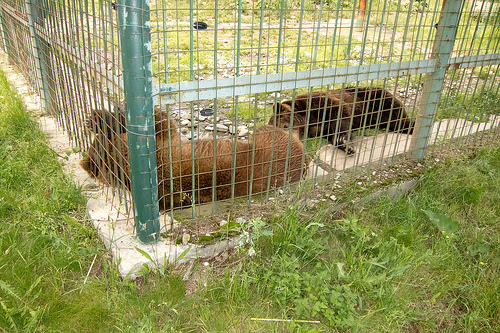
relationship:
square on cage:
[228, 141, 257, 172] [0, 3, 496, 249]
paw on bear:
[388, 114, 406, 131] [268, 84, 411, 155]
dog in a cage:
[71, 95, 290, 204] [155, 0, 408, 203]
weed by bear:
[0, 0, 499, 333] [79, 98, 304, 208]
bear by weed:
[78, 103, 312, 212] [274, 238, 325, 299]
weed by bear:
[0, 0, 499, 333] [72, 91, 296, 204]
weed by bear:
[0, 0, 499, 333] [83, 89, 322, 193]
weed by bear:
[0, 0, 499, 333] [99, 69, 304, 198]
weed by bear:
[339, 225, 419, 294] [63, 95, 313, 202]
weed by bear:
[0, 0, 499, 333] [75, 92, 298, 184]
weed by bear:
[0, 0, 499, 333] [76, 105, 306, 194]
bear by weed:
[68, 79, 315, 214] [417, 185, 457, 249]